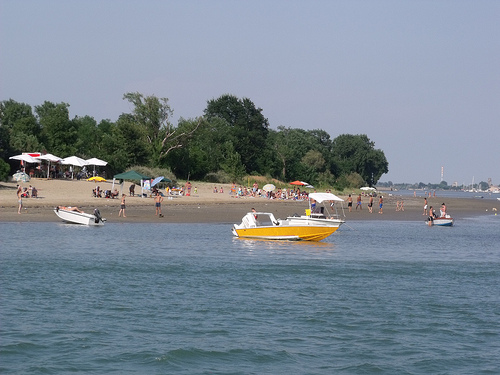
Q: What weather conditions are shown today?
A: It is clear.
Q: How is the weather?
A: It is clear.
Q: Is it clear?
A: Yes, it is clear.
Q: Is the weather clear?
A: Yes, it is clear.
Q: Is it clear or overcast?
A: It is clear.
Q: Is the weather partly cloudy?
A: No, it is clear.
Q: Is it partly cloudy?
A: No, it is clear.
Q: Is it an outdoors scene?
A: Yes, it is outdoors.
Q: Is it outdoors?
A: Yes, it is outdoors.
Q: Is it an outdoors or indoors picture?
A: It is outdoors.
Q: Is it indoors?
A: No, it is outdoors.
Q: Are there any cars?
A: No, there are no cars.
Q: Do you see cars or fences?
A: No, there are no cars or fences.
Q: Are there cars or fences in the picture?
A: No, there are no cars or fences.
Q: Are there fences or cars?
A: No, there are no cars or fences.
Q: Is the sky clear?
A: Yes, the sky is clear.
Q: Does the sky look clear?
A: Yes, the sky is clear.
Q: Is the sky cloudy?
A: No, the sky is clear.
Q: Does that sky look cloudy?
A: No, the sky is clear.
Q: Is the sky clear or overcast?
A: The sky is clear.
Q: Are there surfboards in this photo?
A: No, there are no surfboards.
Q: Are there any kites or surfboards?
A: No, there are no surfboards or kites.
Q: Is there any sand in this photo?
A: Yes, there is sand.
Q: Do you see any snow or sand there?
A: Yes, there is sand.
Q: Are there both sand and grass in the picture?
A: No, there is sand but no grass.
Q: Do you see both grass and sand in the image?
A: No, there is sand but no grass.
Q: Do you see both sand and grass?
A: No, there is sand but no grass.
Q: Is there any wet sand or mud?
A: Yes, there is wet sand.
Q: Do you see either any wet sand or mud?
A: Yes, there is wet sand.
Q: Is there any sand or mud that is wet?
A: Yes, the sand is wet.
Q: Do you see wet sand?
A: Yes, there is wet sand.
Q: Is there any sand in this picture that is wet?
A: Yes, there is sand that is wet.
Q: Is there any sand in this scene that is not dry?
A: Yes, there is wet sand.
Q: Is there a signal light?
A: No, there are no traffic lights.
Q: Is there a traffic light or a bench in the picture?
A: No, there are no traffic lights or benches.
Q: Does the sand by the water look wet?
A: Yes, the sand is wet.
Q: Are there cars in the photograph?
A: No, there are no cars.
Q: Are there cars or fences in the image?
A: No, there are no cars or fences.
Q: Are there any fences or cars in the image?
A: No, there are no cars or fences.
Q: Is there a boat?
A: Yes, there is a boat.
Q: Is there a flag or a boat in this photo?
A: Yes, there is a boat.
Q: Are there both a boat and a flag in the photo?
A: No, there is a boat but no flags.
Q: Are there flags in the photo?
A: No, there are no flags.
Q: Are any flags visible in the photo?
A: No, there are no flags.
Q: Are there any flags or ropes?
A: No, there are no flags or ropes.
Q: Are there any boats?
A: Yes, there is a boat.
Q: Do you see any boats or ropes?
A: Yes, there is a boat.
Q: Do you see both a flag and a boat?
A: No, there is a boat but no flags.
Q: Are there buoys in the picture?
A: No, there are no buoys.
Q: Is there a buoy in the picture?
A: No, there are no buoys.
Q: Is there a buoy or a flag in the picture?
A: No, there are no buoys or flags.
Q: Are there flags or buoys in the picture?
A: No, there are no buoys or flags.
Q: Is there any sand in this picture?
A: Yes, there is sand.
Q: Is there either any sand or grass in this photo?
A: Yes, there is sand.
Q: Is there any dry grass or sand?
A: Yes, there is dry sand.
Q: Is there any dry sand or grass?
A: Yes, there is dry sand.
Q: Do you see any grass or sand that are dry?
A: Yes, the sand is dry.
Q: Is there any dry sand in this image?
A: Yes, there is dry sand.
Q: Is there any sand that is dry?
A: Yes, there is sand that is dry.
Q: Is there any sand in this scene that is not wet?
A: Yes, there is dry sand.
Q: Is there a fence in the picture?
A: No, there are no fences.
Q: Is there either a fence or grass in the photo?
A: No, there are no fences or grass.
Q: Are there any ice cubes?
A: No, there are no ice cubes.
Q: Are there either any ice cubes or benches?
A: No, there are no ice cubes or benches.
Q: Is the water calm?
A: Yes, the water is calm.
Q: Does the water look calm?
A: Yes, the water is calm.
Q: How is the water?
A: The water is calm.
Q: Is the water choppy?
A: No, the water is calm.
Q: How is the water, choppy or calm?
A: The water is calm.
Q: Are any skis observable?
A: No, there are no skis.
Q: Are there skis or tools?
A: No, there are no skis or tools.